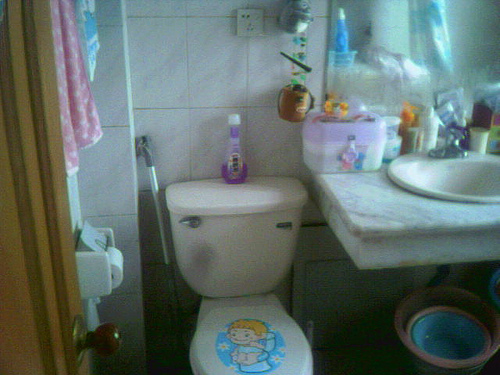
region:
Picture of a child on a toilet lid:
[217, 321, 283, 373]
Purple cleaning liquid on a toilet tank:
[218, 110, 249, 182]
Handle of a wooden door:
[85, 325, 122, 351]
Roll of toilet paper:
[101, 239, 128, 291]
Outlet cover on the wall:
[235, 9, 266, 38]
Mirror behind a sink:
[326, 2, 498, 102]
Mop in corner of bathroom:
[136, 136, 199, 371]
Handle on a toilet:
[179, 215, 201, 230]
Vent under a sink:
[301, 257, 411, 349]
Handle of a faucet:
[449, 128, 466, 148]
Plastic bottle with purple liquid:
[220, 111, 247, 184]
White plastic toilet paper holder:
[74, 224, 124, 301]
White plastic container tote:
[301, 109, 386, 173]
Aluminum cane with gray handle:
[132, 133, 184, 368]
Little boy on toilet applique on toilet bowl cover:
[213, 316, 288, 374]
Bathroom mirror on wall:
[327, 2, 497, 116]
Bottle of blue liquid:
[334, 7, 350, 52]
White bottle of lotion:
[420, 104, 440, 152]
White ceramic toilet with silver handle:
[164, 179, 312, 374]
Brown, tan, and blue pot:
[391, 282, 498, 374]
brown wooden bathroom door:
[5, 1, 127, 374]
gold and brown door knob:
[69, 311, 124, 365]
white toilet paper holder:
[70, 225, 112, 301]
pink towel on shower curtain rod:
[48, 0, 104, 179]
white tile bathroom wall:
[74, 4, 332, 369]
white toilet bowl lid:
[188, 301, 315, 374]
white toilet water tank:
[162, 175, 309, 300]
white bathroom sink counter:
[311, 168, 498, 273]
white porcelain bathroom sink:
[388, 148, 498, 208]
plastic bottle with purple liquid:
[218, 110, 250, 187]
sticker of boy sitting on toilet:
[217, 313, 290, 372]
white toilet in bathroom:
[164, 172, 319, 373]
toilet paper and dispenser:
[75, 216, 122, 333]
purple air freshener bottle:
[223, 111, 250, 182]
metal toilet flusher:
[178, 217, 201, 227]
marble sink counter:
[314, 157, 499, 273]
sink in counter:
[386, 123, 499, 209]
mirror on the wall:
[325, 1, 499, 123]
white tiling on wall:
[78, 0, 143, 367]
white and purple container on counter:
[301, 97, 386, 172]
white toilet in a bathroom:
[160, 156, 322, 371]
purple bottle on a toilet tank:
[209, 101, 260, 196]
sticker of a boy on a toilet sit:
[209, 314, 281, 374]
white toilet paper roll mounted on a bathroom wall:
[76, 222, 146, 314]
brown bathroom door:
[4, 5, 136, 366]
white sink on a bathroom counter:
[396, 111, 498, 218]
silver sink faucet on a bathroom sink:
[414, 103, 473, 170]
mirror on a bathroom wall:
[316, 0, 498, 134]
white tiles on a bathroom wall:
[136, 10, 238, 132]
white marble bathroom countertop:
[341, 171, 411, 250]